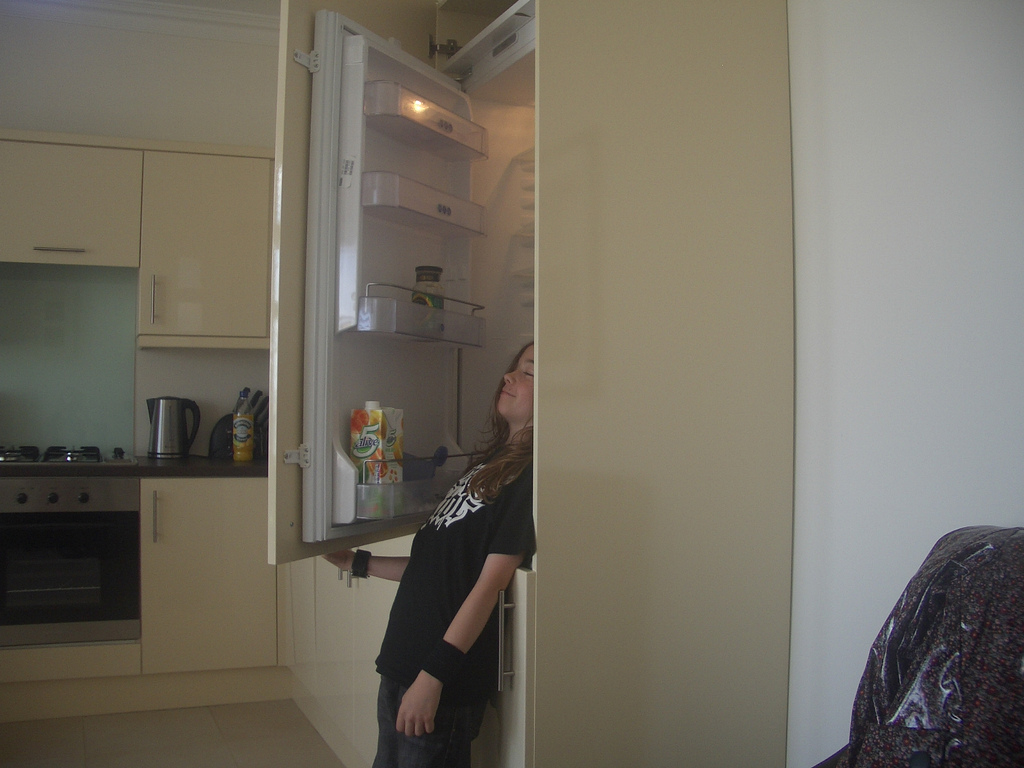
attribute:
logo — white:
[415, 453, 502, 527]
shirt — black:
[371, 441, 536, 707]